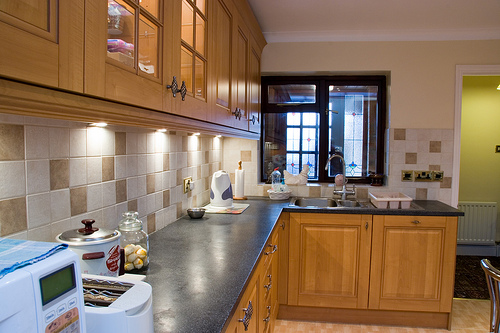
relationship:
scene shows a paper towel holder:
[3, 3, 495, 333] [229, 158, 250, 200]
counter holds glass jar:
[174, 222, 225, 329] [119, 209, 151, 272]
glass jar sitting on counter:
[119, 209, 151, 272] [174, 222, 225, 329]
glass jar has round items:
[119, 209, 151, 272] [127, 241, 146, 271]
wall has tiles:
[394, 49, 430, 130] [395, 131, 452, 195]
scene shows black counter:
[3, 3, 495, 333] [174, 222, 225, 329]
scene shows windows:
[3, 3, 495, 333] [264, 77, 390, 186]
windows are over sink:
[264, 77, 390, 186] [304, 172, 370, 210]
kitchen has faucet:
[3, 3, 495, 333] [336, 176, 358, 204]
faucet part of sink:
[336, 176, 358, 204] [304, 172, 370, 210]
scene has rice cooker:
[3, 3, 495, 333] [66, 219, 127, 278]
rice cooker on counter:
[66, 219, 127, 278] [174, 222, 225, 329]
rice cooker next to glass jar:
[66, 219, 127, 278] [119, 209, 151, 272]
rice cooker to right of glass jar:
[66, 219, 127, 278] [119, 209, 151, 272]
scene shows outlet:
[3, 3, 495, 333] [182, 181, 196, 197]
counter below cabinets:
[174, 222, 225, 329] [1, 10, 263, 141]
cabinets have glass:
[1, 10, 263, 141] [112, 12, 138, 64]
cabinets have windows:
[1, 10, 263, 141] [180, 10, 213, 97]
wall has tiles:
[9, 124, 160, 201] [395, 131, 452, 195]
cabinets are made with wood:
[1, 10, 263, 141] [4, 3, 95, 74]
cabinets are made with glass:
[1, 10, 263, 141] [112, 12, 138, 64]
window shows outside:
[264, 77, 390, 186] [333, 102, 363, 169]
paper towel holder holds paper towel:
[229, 158, 250, 200] [234, 170, 245, 198]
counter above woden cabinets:
[174, 222, 225, 329] [293, 223, 451, 332]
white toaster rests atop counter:
[88, 277, 161, 332] [174, 222, 225, 329]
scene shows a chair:
[3, 3, 495, 333] [470, 254, 496, 332]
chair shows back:
[470, 254, 496, 332] [482, 265, 498, 329]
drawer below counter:
[260, 219, 288, 273] [174, 222, 225, 329]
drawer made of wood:
[260, 219, 288, 273] [4, 3, 95, 74]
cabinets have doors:
[1, 10, 263, 141] [374, 223, 453, 317]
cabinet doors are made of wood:
[290, 215, 378, 325] [4, 3, 95, 74]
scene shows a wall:
[3, 3, 495, 333] [394, 49, 430, 130]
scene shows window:
[3, 3, 495, 333] [328, 87, 386, 187]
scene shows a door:
[3, 3, 495, 333] [454, 69, 499, 264]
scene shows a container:
[3, 3, 495, 333] [119, 209, 151, 272]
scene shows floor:
[3, 3, 495, 333] [460, 261, 486, 328]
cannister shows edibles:
[119, 209, 151, 272] [129, 245, 147, 266]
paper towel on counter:
[234, 170, 245, 198] [174, 222, 225, 329]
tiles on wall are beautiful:
[395, 131, 452, 195] [394, 132, 439, 159]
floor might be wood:
[460, 261, 486, 328] [4, 3, 95, 74]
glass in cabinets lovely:
[112, 12, 138, 64] [110, 12, 166, 82]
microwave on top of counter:
[1, 237, 92, 331] [174, 222, 225, 329]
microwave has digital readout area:
[1, 237, 92, 331] [39, 268, 80, 306]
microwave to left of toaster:
[1, 237, 92, 331] [88, 277, 161, 332]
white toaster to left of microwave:
[88, 277, 161, 332] [1, 237, 92, 331]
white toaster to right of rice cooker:
[88, 277, 161, 332] [66, 219, 127, 278]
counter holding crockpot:
[174, 222, 225, 329] [66, 219, 127, 278]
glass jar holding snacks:
[119, 209, 151, 272] [127, 241, 146, 271]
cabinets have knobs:
[1, 10, 263, 141] [166, 77, 189, 101]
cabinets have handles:
[290, 215, 378, 325] [237, 302, 263, 325]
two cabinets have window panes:
[109, 2, 214, 100] [180, 10, 213, 97]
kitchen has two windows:
[3, 3, 495, 333] [264, 77, 390, 186]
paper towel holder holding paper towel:
[229, 158, 250, 200] [234, 170, 245, 198]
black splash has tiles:
[9, 124, 160, 201] [395, 131, 452, 195]